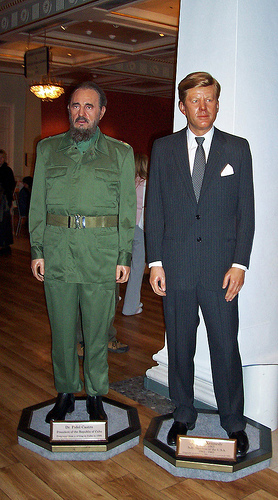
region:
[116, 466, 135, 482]
part of a floor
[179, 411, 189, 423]
part of a trouser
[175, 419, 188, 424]
edge of a trouser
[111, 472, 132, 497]
part of a floor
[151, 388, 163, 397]
edge of a wall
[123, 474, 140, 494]
part of a floor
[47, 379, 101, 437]
black shoes are visible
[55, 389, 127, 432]
black shoes are visible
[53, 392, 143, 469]
black shoes are visible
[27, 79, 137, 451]
Fidel castro figure in green uniform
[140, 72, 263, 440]
president kennedy figure in black suit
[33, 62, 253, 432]
two figures of presidents in different countries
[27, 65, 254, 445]
ex president of Cuba and Expresident of United States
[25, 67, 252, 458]
two mens one in a suit and one in green uniform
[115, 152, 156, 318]
blonde woman with blue jeans and white t-shirt on the back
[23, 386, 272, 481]
two grey bases where figures of presidents are standing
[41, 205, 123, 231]
olive green belt in Fidel Castro Uniform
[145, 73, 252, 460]
blonde men with grey tie and black suit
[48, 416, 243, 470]
two plates where Fidel Castro and John F. Kennedy is written on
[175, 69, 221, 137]
a man with a shiny face.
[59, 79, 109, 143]
a man with an old face.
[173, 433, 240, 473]
a plaque on a statute.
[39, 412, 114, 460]
a plaque on a display.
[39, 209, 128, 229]
a belt on a man's waist.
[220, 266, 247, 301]
a man's left hand.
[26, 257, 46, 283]
a man's right hand.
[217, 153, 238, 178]
a handkerchief in a pocket.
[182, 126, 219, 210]
a neck tie around a man's neck.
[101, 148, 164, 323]
a woman standing behind two men.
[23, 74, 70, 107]
a light hanging from the ceiling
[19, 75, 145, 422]
a wax statue of Fidel Castro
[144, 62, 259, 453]
a wax statue of Kennedy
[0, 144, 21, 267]
a person wearing black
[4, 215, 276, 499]
a hardwood floor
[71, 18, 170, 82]
decorative trays in a ceiling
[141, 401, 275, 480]
a pedestal for a wax statue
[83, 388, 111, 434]
a shoe on a wax statue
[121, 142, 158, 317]
a woman in gray pants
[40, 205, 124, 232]
a belt on a wax statue